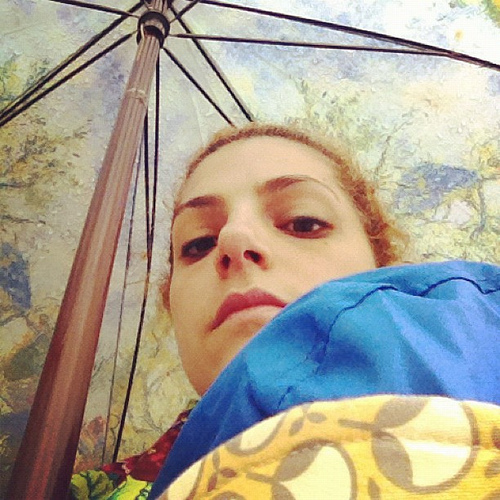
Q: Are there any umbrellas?
A: Yes, there is an umbrella.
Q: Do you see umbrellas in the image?
A: Yes, there is an umbrella.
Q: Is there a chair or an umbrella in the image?
A: Yes, there is an umbrella.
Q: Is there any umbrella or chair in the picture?
A: Yes, there is an umbrella.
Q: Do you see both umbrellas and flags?
A: No, there is an umbrella but no flags.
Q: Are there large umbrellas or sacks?
A: Yes, there is a large umbrella.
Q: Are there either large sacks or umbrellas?
A: Yes, there is a large umbrella.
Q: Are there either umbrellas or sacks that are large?
A: Yes, the umbrella is large.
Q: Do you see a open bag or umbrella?
A: Yes, there is an open umbrella.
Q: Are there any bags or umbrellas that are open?
A: Yes, the umbrella is open.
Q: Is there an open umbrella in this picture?
A: Yes, there is an open umbrella.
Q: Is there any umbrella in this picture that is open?
A: Yes, there is an umbrella that is open.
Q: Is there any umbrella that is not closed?
A: Yes, there is a open umbrella.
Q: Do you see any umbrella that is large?
A: Yes, there is a large umbrella.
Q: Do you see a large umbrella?
A: Yes, there is a large umbrella.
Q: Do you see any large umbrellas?
A: Yes, there is a large umbrella.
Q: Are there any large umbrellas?
A: Yes, there is a large umbrella.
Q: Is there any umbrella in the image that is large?
A: Yes, there is an umbrella that is large.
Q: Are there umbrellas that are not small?
A: Yes, there is a large umbrella.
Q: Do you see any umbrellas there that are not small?
A: Yes, there is a large umbrella.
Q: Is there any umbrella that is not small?
A: Yes, there is a large umbrella.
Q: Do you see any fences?
A: No, there are no fences.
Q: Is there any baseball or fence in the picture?
A: No, there are no fences or baseballs.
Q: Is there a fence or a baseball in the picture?
A: No, there are no fences or baseballs.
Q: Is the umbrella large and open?
A: Yes, the umbrella is large and open.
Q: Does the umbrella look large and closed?
A: No, the umbrella is large but open.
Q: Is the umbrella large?
A: Yes, the umbrella is large.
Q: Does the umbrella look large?
A: Yes, the umbrella is large.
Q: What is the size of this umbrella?
A: The umbrella is large.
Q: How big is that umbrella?
A: The umbrella is large.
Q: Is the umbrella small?
A: No, the umbrella is large.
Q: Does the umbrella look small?
A: No, the umbrella is large.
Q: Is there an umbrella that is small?
A: No, there is an umbrella but it is large.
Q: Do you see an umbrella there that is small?
A: No, there is an umbrella but it is large.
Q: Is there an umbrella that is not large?
A: No, there is an umbrella but it is large.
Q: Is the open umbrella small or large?
A: The umbrella is large.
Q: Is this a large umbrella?
A: Yes, this is a large umbrella.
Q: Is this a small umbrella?
A: No, this is a large umbrella.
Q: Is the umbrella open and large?
A: Yes, the umbrella is open and large.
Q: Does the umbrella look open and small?
A: No, the umbrella is open but large.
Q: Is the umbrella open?
A: Yes, the umbrella is open.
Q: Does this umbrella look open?
A: Yes, the umbrella is open.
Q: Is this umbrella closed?
A: No, the umbrella is open.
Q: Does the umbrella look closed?
A: No, the umbrella is open.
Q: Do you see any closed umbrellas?
A: No, there is an umbrella but it is open.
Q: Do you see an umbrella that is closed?
A: No, there is an umbrella but it is open.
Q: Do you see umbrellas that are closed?
A: No, there is an umbrella but it is open.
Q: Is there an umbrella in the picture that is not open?
A: No, there is an umbrella but it is open.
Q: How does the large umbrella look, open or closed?
A: The umbrella is open.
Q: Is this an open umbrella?
A: Yes, this is an open umbrella.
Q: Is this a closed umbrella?
A: No, this is an open umbrella.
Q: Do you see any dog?
A: No, there are no dogs.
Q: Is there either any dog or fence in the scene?
A: No, there are no dogs or fences.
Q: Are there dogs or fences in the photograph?
A: No, there are no dogs or fences.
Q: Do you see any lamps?
A: No, there are no lamps.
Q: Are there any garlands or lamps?
A: No, there are no lamps or garlands.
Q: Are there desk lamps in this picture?
A: No, there are no desk lamps.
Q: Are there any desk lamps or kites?
A: No, there are no desk lamps or kites.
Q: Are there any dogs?
A: No, there are no dogs.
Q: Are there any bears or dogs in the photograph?
A: No, there are no dogs or bears.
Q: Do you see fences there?
A: No, there are no fences.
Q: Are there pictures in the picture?
A: No, there are no pictures.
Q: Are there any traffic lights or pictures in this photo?
A: No, there are no pictures or traffic lights.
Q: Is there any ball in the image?
A: No, there are no balls.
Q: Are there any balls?
A: No, there are no balls.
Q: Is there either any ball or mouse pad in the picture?
A: No, there are no balls or mouse pads.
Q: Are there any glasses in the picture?
A: No, there are no glasses.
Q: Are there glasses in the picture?
A: No, there are no glasses.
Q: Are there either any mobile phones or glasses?
A: No, there are no glasses or mobile phones.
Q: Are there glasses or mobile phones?
A: No, there are no glasses or mobile phones.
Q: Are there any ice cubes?
A: No, there are no ice cubes.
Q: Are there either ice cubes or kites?
A: No, there are no ice cubes or kites.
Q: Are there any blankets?
A: Yes, there is a blanket.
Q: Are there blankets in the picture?
A: Yes, there is a blanket.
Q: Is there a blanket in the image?
A: Yes, there is a blanket.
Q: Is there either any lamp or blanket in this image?
A: Yes, there is a blanket.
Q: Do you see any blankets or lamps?
A: Yes, there is a blanket.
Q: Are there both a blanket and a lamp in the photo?
A: No, there is a blanket but no lamps.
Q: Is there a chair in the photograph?
A: No, there are no chairs.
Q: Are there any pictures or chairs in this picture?
A: No, there are no chairs or pictures.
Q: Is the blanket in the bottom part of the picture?
A: Yes, the blanket is in the bottom of the image.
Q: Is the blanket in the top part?
A: No, the blanket is in the bottom of the image.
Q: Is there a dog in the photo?
A: No, there are no dogs.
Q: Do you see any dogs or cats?
A: No, there are no dogs or cats.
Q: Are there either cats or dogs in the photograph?
A: No, there are no dogs or cats.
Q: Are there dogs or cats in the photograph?
A: No, there are no dogs or cats.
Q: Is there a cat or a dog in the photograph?
A: No, there are no dogs or cats.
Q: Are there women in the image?
A: Yes, there is a woman.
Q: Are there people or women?
A: Yes, there is a woman.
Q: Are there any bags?
A: No, there are no bags.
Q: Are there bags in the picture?
A: No, there are no bags.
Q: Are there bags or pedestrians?
A: No, there are no bags or pedestrians.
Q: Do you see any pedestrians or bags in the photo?
A: No, there are no bags or pedestrians.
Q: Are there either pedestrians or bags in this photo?
A: No, there are no bags or pedestrians.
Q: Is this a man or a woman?
A: This is a woman.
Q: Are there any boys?
A: No, there are no boys.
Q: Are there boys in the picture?
A: No, there are no boys.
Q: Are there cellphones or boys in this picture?
A: No, there are no boys or cellphones.